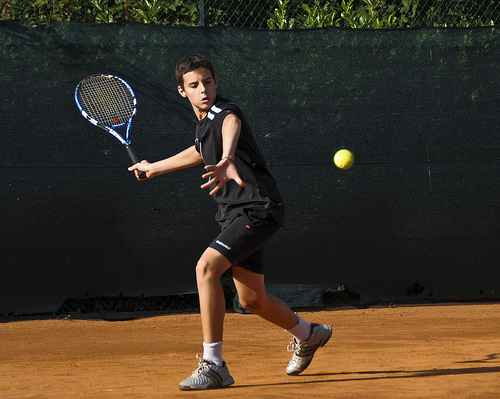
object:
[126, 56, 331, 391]
man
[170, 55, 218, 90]
hair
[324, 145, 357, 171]
tennis ball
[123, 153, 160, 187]
man's hand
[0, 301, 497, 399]
tennis court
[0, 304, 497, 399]
dirt ground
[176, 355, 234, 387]
left sneaker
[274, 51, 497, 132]
green screen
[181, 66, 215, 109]
face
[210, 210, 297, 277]
black shorts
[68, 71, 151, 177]
tennis racket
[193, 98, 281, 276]
black outfit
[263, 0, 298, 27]
foliage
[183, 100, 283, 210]
tank top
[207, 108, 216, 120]
white stripes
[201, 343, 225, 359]
white socks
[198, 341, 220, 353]
ankle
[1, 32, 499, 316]
black cover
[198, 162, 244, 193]
left hand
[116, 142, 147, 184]
black handle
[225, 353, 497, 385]
black shadow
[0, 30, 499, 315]
green tarp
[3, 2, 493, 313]
metal fence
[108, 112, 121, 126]
dot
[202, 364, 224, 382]
logo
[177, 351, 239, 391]
sneaker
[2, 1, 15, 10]
leaves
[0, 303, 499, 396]
dirt